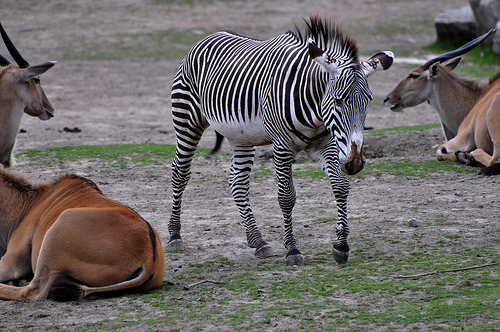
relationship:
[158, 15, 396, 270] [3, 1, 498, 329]
zebra in field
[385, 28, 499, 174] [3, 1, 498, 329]
giselle laying on ground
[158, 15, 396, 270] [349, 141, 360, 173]
zebra has nose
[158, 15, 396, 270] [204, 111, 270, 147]
zebra has stomach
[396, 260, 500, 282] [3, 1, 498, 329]
branch on field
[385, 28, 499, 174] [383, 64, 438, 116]
giselle has head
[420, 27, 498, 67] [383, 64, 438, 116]
horns top of head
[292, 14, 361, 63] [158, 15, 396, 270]
mane on zebra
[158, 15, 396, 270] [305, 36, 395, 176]
zebra has head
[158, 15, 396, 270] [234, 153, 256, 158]
zebra has stripe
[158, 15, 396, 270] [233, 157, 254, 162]
zebra has stripe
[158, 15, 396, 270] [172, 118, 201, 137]
zebra has stripe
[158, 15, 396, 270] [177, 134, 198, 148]
zebra has stripe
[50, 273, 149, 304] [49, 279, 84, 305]
tail has end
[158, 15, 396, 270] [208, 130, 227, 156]
zebra has tail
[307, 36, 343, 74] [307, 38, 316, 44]
ear has tip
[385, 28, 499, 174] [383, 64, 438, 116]
gazelle has face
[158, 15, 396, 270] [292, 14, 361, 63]
zebra has mane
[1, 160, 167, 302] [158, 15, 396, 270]
animal near zebra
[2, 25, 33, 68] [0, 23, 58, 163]
horn on animal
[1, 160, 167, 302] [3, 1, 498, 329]
animal laying on field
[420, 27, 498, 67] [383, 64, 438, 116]
horns on head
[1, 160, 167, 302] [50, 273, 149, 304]
animal has tail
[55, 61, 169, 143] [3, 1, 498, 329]
patch on field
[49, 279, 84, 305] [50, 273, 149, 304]
end of tail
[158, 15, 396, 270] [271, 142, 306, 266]
zebra has leg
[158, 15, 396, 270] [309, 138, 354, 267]
zebra has leg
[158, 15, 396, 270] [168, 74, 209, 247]
zebra has leg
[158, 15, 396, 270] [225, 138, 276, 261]
zebra has leg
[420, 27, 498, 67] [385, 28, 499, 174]
horns of gazelle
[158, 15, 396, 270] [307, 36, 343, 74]
zebra has ear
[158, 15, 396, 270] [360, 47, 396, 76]
zebra has ear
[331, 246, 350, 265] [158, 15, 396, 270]
hoof of zebra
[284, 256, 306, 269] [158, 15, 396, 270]
hoof of zebra